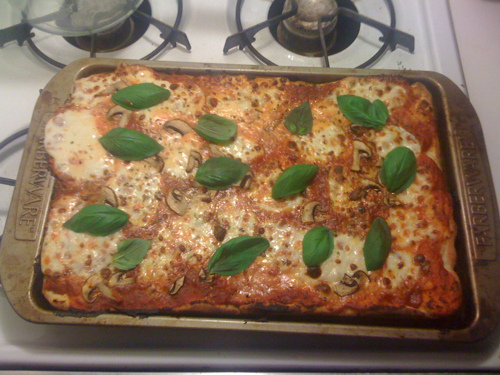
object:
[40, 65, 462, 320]
pizza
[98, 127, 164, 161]
leaf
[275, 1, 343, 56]
burner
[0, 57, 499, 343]
pan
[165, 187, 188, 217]
mushrooms